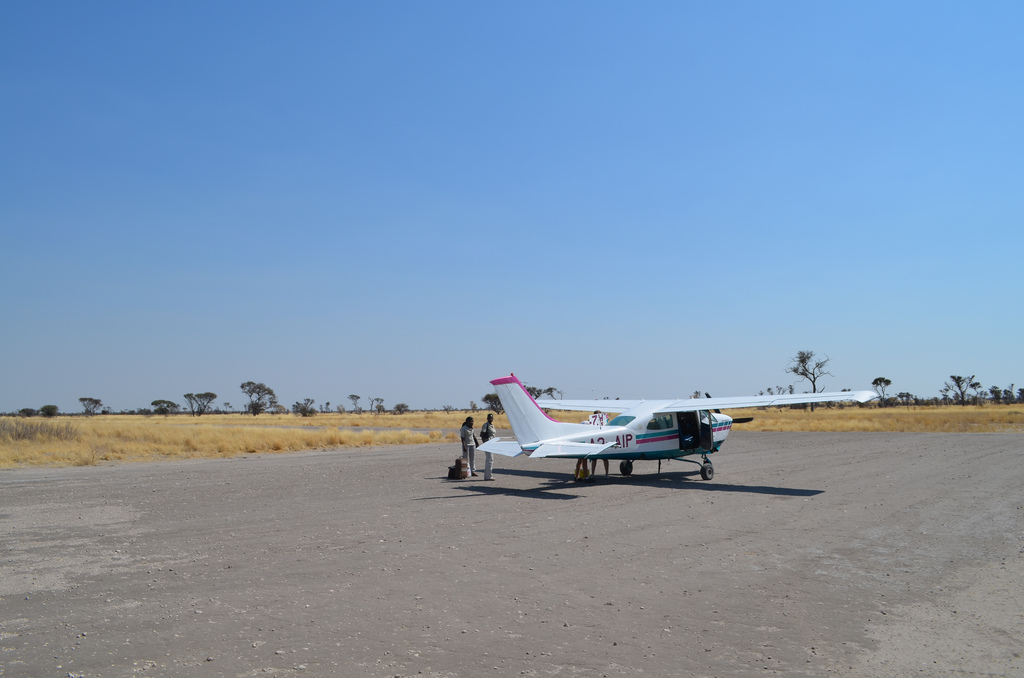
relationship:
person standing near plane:
[458, 416, 478, 476] [474, 376, 896, 511]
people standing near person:
[479, 413, 496, 481] [458, 416, 478, 476]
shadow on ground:
[411, 468, 825, 500] [0, 403, 1022, 674]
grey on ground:
[0, 423, 1024, 678] [0, 403, 1022, 674]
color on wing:
[479, 367, 538, 400] [477, 369, 596, 450]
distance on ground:
[0, 350, 1024, 472] [0, 403, 1022, 674]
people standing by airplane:
[432, 392, 525, 499] [476, 373, 879, 480]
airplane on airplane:
[476, 373, 879, 480] [476, 373, 879, 480]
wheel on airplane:
[700, 444, 748, 496] [476, 373, 879, 480]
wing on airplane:
[671, 379, 913, 438] [476, 373, 879, 480]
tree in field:
[941, 365, 1000, 405] [12, 351, 1021, 507]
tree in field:
[62, 380, 127, 430] [2, 356, 1020, 475]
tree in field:
[862, 367, 910, 424] [12, 351, 1021, 507]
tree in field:
[533, 379, 583, 416] [2, 356, 1020, 475]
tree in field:
[468, 377, 529, 419] [8, 364, 1022, 485]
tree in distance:
[885, 380, 925, 409] [4, 360, 1022, 488]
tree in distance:
[397, 401, 423, 419] [13, 347, 1022, 503]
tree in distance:
[356, 393, 393, 433] [8, 339, 1022, 512]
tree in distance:
[323, 380, 375, 417] [13, 347, 1022, 503]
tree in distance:
[280, 392, 333, 423] [13, 347, 1022, 503]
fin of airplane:
[476, 373, 637, 447] [456, 366, 867, 479]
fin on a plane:
[472, 370, 598, 477] [427, 333, 877, 526]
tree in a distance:
[74, 377, 111, 417] [0, 350, 1024, 472]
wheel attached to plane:
[687, 443, 737, 491] [474, 348, 883, 469]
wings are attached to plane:
[498, 385, 916, 420] [463, 359, 881, 487]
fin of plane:
[476, 373, 637, 447] [415, 339, 813, 592]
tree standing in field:
[35, 402, 62, 418] [4, 398, 992, 461]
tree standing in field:
[147, 396, 182, 414] [2, 402, 992, 467]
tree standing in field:
[181, 390, 199, 416] [2, 402, 992, 467]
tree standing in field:
[199, 389, 217, 416] [2, 402, 992, 467]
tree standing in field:
[238, 379, 260, 410] [2, 402, 992, 467]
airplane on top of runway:
[476, 373, 879, 480] [39, 420, 1022, 652]